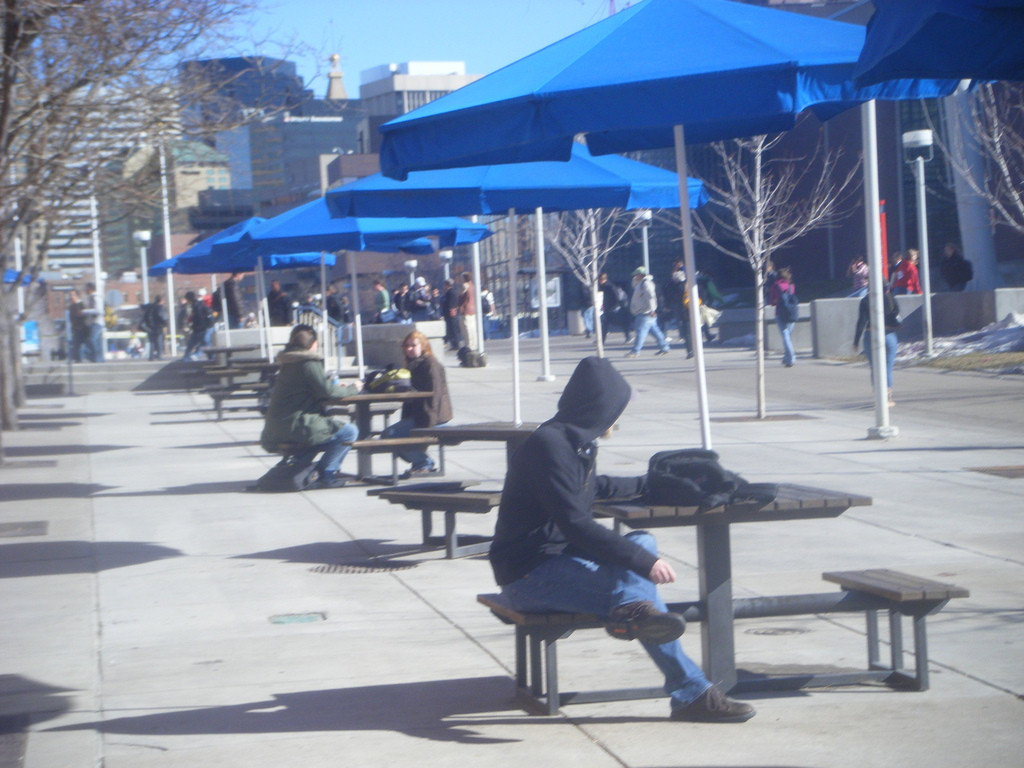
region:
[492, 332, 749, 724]
person sitting down in the black hoodie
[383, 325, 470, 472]
the woman sitting down with red hair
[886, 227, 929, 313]
person in red walking into the building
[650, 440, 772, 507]
The black thing on the table with the guy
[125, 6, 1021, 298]
All of the blue umbrellas over the tables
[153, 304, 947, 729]
All of the tables and benches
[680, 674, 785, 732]
The guys shoe that is on the ground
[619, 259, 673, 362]
man in hat walking with hands in pocket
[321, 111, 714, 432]
blue umbrella open over table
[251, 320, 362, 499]
woman in blue jeans sitting at table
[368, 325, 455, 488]
woman in black jacket sitting outside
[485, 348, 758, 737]
man in black jacket sitting at table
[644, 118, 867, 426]
leaveless tree planted in sidewalk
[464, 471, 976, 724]
wood and metal table and seats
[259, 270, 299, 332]
man in black jacket standing on sidewalk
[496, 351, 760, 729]
person in a black hoodie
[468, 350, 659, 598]
long sleeved black hoodie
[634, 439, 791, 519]
black bag on a table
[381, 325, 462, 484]
person with red hair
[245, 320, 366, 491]
person with a green jacket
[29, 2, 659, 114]
clear blue colored sky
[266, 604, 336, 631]
drain in the sidewalk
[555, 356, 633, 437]
hood on a black jacket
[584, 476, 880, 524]
table top under a black bag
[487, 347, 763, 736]
person sitting alone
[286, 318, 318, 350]
person has a head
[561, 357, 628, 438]
person has a head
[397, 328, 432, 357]
person has a head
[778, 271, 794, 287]
person has a head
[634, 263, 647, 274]
person has a head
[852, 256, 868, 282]
person has a head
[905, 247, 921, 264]
person has a head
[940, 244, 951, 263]
person has a head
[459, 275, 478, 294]
person has a head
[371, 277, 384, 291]
person has a head